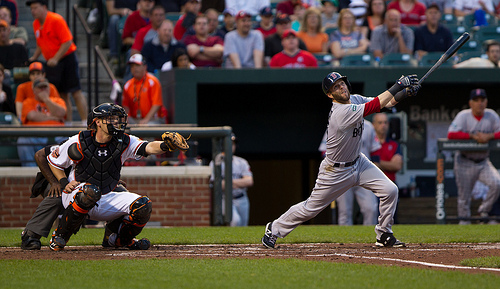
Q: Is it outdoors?
A: Yes, it is outdoors.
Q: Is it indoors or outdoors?
A: It is outdoors.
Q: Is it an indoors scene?
A: No, it is outdoors.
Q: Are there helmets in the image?
A: Yes, there is a helmet.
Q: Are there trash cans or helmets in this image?
A: Yes, there is a helmet.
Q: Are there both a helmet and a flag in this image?
A: No, there is a helmet but no flags.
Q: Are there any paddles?
A: No, there are no paddles.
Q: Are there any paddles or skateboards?
A: No, there are no paddles or skateboards.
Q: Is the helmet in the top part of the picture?
A: Yes, the helmet is in the top of the image.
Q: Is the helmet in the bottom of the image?
A: No, the helmet is in the top of the image.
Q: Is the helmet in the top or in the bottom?
A: The helmet is in the top of the image.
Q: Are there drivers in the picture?
A: No, there are no drivers.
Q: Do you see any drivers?
A: No, there are no drivers.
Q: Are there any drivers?
A: No, there are no drivers.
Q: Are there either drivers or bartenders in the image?
A: No, there are no drivers or bartenders.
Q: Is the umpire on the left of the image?
A: Yes, the umpire is on the left of the image.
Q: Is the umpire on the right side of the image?
A: No, the umpire is on the left of the image.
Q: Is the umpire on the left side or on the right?
A: The umpire is on the left of the image.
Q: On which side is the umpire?
A: The umpire is on the left of the image.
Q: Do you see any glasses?
A: No, there are no glasses.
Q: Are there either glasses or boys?
A: No, there are no glasses or boys.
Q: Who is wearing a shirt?
A: The man is wearing a shirt.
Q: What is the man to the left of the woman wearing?
A: The man is wearing a shirt.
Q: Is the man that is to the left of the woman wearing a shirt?
A: Yes, the man is wearing a shirt.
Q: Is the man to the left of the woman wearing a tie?
A: No, the man is wearing a shirt.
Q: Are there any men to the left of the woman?
A: Yes, there is a man to the left of the woman.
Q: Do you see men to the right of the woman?
A: No, the man is to the left of the woman.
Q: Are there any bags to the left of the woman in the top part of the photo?
A: No, there is a man to the left of the woman.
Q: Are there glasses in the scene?
A: No, there are no glasses.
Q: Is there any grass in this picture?
A: Yes, there is grass.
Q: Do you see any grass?
A: Yes, there is grass.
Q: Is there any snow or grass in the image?
A: Yes, there is grass.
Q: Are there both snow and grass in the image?
A: No, there is grass but no snow.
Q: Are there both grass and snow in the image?
A: No, there is grass but no snow.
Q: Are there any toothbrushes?
A: No, there are no toothbrushes.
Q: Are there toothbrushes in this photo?
A: No, there are no toothbrushes.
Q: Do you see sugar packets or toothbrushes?
A: No, there are no toothbrushes or sugar packets.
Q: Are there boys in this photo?
A: No, there are no boys.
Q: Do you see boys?
A: No, there are no boys.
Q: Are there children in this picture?
A: No, there are no children.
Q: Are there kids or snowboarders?
A: No, there are no kids or snowboarders.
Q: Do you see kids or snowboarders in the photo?
A: No, there are no kids or snowboarders.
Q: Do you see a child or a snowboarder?
A: No, there are no children or snowboarders.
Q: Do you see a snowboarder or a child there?
A: No, there are no children or snowboarders.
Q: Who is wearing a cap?
A: The man is wearing a cap.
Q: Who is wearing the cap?
A: The man is wearing a cap.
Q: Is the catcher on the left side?
A: Yes, the catcher is on the left of the image.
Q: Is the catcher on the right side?
A: No, the catcher is on the left of the image.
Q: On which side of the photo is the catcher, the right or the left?
A: The catcher is on the left of the image.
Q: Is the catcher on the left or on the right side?
A: The catcher is on the left of the image.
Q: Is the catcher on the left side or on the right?
A: The catcher is on the left of the image.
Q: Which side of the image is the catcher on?
A: The catcher is on the left of the image.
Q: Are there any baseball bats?
A: Yes, there is a baseball bat.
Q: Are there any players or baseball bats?
A: Yes, there is a baseball bat.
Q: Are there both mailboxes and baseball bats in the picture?
A: No, there is a baseball bat but no mailboxes.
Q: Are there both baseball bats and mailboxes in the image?
A: No, there is a baseball bat but no mailboxes.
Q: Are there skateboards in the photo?
A: No, there are no skateboards.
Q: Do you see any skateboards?
A: No, there are no skateboards.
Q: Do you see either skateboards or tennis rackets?
A: No, there are no skateboards or tennis rackets.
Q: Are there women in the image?
A: Yes, there is a woman.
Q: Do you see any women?
A: Yes, there is a woman.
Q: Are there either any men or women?
A: Yes, there is a woman.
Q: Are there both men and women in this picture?
A: Yes, there are both a woman and a man.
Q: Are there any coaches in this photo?
A: No, there are no coaches.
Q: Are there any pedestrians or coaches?
A: No, there are no coaches or pedestrians.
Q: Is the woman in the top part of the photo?
A: Yes, the woman is in the top of the image.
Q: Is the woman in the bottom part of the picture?
A: No, the woman is in the top of the image.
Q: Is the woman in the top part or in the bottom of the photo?
A: The woman is in the top of the image.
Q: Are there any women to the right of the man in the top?
A: Yes, there is a woman to the right of the man.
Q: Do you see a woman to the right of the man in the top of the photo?
A: Yes, there is a woman to the right of the man.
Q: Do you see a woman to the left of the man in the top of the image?
A: No, the woman is to the right of the man.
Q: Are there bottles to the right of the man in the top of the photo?
A: No, there is a woman to the right of the man.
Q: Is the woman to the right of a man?
A: Yes, the woman is to the right of a man.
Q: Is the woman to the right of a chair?
A: No, the woman is to the right of a man.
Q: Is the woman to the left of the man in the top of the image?
A: No, the woman is to the right of the man.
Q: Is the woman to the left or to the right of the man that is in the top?
A: The woman is to the right of the man.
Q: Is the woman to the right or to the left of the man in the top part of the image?
A: The woman is to the right of the man.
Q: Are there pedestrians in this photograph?
A: No, there are no pedestrians.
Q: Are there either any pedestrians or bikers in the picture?
A: No, there are no pedestrians or bikers.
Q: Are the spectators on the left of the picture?
A: Yes, the spectators are on the left of the image.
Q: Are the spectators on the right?
A: No, the spectators are on the left of the image.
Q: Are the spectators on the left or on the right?
A: The spectators are on the left of the image.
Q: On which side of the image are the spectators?
A: The spectators are on the left of the image.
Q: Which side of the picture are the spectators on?
A: The spectators are on the left of the image.